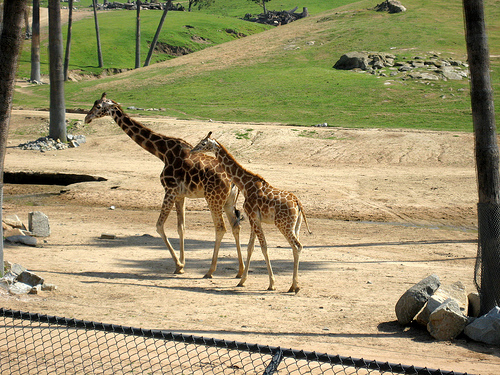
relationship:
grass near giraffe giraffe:
[6, 0, 495, 138] [188, 128, 313, 292]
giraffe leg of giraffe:
[281, 227, 303, 293] [194, 130, 317, 300]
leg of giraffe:
[246, 206, 281, 292] [52, 46, 252, 242]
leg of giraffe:
[238, 204, 257, 286] [188, 128, 313, 292]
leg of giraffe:
[221, 189, 251, 279] [84, 90, 253, 282]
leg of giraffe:
[152, 187, 187, 277] [84, 90, 253, 282]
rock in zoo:
[397, 280, 498, 350] [6, 3, 496, 369]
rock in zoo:
[23, 213, 53, 244] [6, 3, 496, 369]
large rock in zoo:
[429, 297, 466, 337] [6, 3, 496, 369]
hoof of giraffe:
[235, 281, 248, 290] [188, 128, 313, 292]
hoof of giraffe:
[266, 280, 280, 291] [188, 128, 313, 292]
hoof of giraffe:
[288, 286, 294, 293] [188, 128, 313, 292]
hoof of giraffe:
[293, 286, 301, 296] [188, 128, 313, 292]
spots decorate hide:
[172, 157, 209, 184] [113, 111, 243, 223]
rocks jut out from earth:
[332, 44, 469, 86] [18, 5, 492, 369]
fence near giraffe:
[3, 310, 484, 373] [166, 114, 365, 280]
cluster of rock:
[386, 270, 494, 353] [387, 273, 437, 322]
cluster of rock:
[386, 270, 494, 353] [422, 286, 463, 317]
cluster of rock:
[386, 270, 494, 353] [422, 296, 466, 338]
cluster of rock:
[386, 270, 494, 353] [466, 286, 485, 317]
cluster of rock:
[386, 270, 494, 353] [462, 303, 495, 355]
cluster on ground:
[386, 270, 494, 353] [312, 152, 430, 232]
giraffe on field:
[188, 128, 313, 292] [6, 6, 492, 371]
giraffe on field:
[84, 90, 253, 282] [6, 6, 492, 371]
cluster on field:
[327, 38, 492, 110] [37, 5, 498, 141]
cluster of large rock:
[327, 38, 492, 110] [330, 45, 475, 99]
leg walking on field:
[202, 200, 226, 281] [307, 80, 469, 263]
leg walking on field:
[152, 187, 187, 277] [307, 80, 469, 263]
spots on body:
[172, 157, 209, 184] [77, 88, 234, 282]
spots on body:
[114, 109, 193, 169] [77, 88, 234, 282]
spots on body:
[249, 185, 279, 213] [187, 129, 329, 304]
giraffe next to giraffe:
[188, 128, 313, 292] [84, 90, 253, 282]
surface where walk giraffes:
[16, 166, 491, 367] [83, 76, 323, 300]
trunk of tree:
[6, 3, 24, 187] [0, 0, 38, 174]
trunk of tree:
[31, 4, 44, 73] [16, 3, 47, 82]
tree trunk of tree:
[46, 0, 69, 147] [25, 4, 86, 144]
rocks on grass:
[332, 44, 469, 86] [6, 0, 495, 138]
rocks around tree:
[18, 126, 99, 166] [40, 0, 69, 136]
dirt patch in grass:
[146, 35, 191, 60] [238, 48, 359, 101]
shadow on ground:
[62, 211, 304, 296] [2, 0, 499, 372]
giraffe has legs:
[185, 109, 315, 298] [233, 203, 274, 292]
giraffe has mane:
[188, 128, 313, 292] [214, 138, 265, 181]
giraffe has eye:
[84, 90, 253, 282] [94, 100, 105, 113]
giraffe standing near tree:
[188, 128, 313, 292] [460, 0, 498, 313]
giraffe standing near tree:
[84, 90, 253, 282] [460, 0, 498, 313]